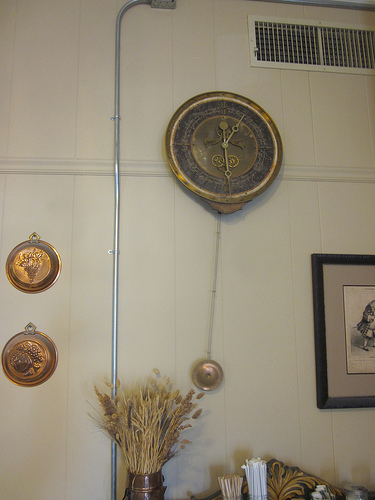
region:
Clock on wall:
[172, 80, 287, 225]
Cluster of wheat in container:
[87, 376, 201, 498]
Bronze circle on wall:
[7, 324, 57, 384]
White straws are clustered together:
[235, 445, 277, 498]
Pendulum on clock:
[202, 213, 233, 395]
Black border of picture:
[305, 241, 334, 407]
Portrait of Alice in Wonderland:
[345, 287, 374, 363]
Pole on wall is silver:
[112, 185, 119, 393]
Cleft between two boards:
[170, 190, 182, 496]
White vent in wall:
[240, 41, 374, 68]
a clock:
[226, 94, 358, 207]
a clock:
[129, 121, 280, 284]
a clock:
[171, 107, 327, 292]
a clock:
[190, 126, 262, 223]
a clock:
[133, 103, 308, 206]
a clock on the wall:
[161, 56, 332, 403]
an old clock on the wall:
[110, 49, 284, 429]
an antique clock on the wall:
[132, 55, 310, 428]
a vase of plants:
[81, 343, 222, 498]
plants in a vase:
[85, 368, 235, 497]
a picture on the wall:
[271, 214, 366, 361]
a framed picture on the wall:
[259, 216, 366, 422]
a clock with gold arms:
[140, 54, 321, 281]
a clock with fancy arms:
[133, 30, 283, 271]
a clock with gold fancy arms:
[129, 56, 325, 246]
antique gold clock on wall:
[170, 103, 301, 208]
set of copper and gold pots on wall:
[11, 238, 74, 406]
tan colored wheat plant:
[57, 347, 220, 473]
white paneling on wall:
[228, 257, 279, 400]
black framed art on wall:
[302, 228, 366, 414]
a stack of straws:
[245, 448, 274, 498]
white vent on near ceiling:
[245, 12, 372, 77]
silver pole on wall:
[106, 182, 123, 383]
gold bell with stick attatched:
[187, 237, 264, 439]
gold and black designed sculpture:
[268, 450, 319, 497]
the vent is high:
[244, 9, 372, 73]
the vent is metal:
[243, 8, 373, 70]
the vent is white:
[247, 10, 372, 78]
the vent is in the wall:
[245, 9, 367, 76]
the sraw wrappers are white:
[237, 453, 273, 494]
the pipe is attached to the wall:
[100, 233, 125, 356]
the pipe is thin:
[105, 72, 130, 363]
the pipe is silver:
[107, 27, 131, 380]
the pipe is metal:
[104, 72, 130, 376]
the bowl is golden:
[1, 318, 64, 390]